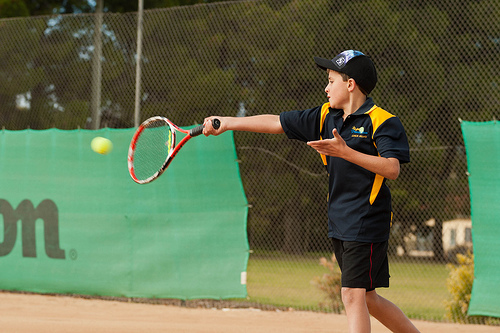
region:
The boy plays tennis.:
[120, 40, 447, 331]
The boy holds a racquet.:
[117, 99, 232, 191]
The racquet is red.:
[117, 100, 229, 192]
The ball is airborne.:
[76, 127, 123, 163]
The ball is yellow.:
[80, 125, 122, 160]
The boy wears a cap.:
[299, 40, 394, 98]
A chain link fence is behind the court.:
[0, 1, 495, 133]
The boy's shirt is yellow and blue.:
[285, 92, 405, 245]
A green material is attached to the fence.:
[0, 111, 252, 300]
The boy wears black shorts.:
[324, 213, 396, 295]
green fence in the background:
[146, 36, 276, 75]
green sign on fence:
[63, 168, 185, 233]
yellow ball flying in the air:
[79, 129, 122, 167]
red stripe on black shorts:
[348, 235, 392, 295]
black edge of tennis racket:
[209, 118, 234, 138]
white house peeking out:
[432, 213, 479, 255]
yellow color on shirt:
[343, 98, 393, 148]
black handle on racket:
[177, 112, 236, 155]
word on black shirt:
[344, 122, 386, 152]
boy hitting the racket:
[100, 36, 421, 253]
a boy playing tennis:
[68, 40, 440, 331]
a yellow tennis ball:
[76, 120, 113, 162]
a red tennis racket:
[113, 107, 206, 187]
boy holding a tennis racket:
[117, 97, 277, 182]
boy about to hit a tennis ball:
[67, 30, 444, 225]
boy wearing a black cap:
[301, 37, 383, 93]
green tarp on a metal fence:
[173, 175, 280, 300]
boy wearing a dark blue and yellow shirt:
[261, 102, 415, 224]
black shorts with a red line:
[321, 226, 413, 293]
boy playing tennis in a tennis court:
[73, 42, 438, 327]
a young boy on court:
[202, 39, 427, 329]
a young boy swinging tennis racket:
[127, 44, 417, 331]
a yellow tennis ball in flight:
[90, 129, 110, 155]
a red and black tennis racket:
[120, 111, 225, 184]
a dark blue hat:
[308, 41, 374, 92]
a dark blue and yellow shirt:
[277, 102, 404, 232]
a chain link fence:
[1, 14, 497, 325]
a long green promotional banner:
[2, 120, 252, 305]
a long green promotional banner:
[455, 117, 499, 319]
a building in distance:
[404, 210, 471, 260]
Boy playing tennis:
[115, 62, 450, 306]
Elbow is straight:
[254, 99, 302, 141]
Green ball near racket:
[91, 123, 125, 163]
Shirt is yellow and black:
[283, 90, 428, 277]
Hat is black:
[324, 37, 378, 89]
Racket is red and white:
[118, 107, 215, 174]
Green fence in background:
[2, 125, 251, 292]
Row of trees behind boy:
[11, 9, 493, 92]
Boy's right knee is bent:
[365, 289, 399, 309]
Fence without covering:
[408, 148, 465, 313]